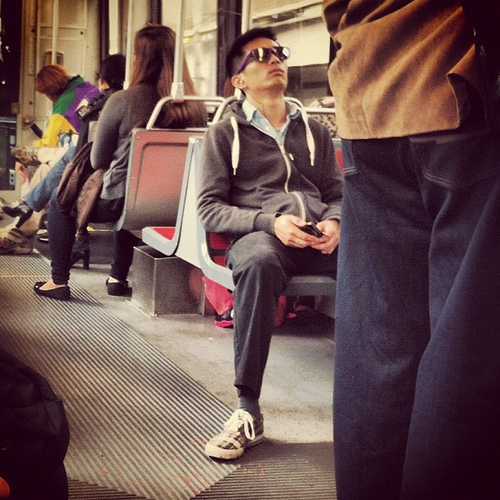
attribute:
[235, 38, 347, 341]
man — sleeping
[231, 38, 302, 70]
sunglasses — black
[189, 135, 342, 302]
chair — silver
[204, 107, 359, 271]
hoodie — grey, gray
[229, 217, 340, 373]
pants — grey, blue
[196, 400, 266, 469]
shoes — plaid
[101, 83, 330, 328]
seats — metal, metallic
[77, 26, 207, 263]
woman — sitting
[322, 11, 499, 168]
jacket — brown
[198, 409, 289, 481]
sneakers — plaid, plait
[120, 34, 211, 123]
hair — long, auburn, brown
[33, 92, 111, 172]
jacket — purple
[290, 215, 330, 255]
phone — cell, black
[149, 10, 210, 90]
pole — metal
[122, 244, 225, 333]
box — metal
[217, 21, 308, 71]
hair — black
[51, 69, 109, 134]
coat — purple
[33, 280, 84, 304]
slipper — black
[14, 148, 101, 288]
jeans — blue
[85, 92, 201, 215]
shirt — gray